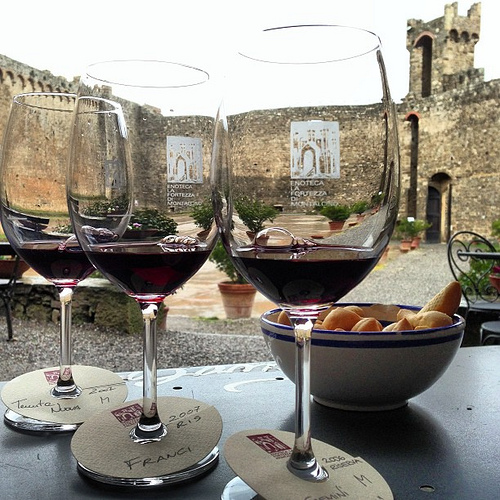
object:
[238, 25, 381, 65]
mouth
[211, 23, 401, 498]
glass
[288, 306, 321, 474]
stem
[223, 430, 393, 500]
base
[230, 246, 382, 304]
wine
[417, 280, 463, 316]
bread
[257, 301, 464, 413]
bowl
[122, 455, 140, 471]
writing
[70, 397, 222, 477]
paper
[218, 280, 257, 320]
pot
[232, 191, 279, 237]
plant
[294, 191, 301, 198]
writing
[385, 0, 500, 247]
wall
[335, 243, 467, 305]
floor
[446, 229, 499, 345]
chair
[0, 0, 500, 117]
sky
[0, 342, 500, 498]
table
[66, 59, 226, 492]
glass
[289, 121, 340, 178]
logo